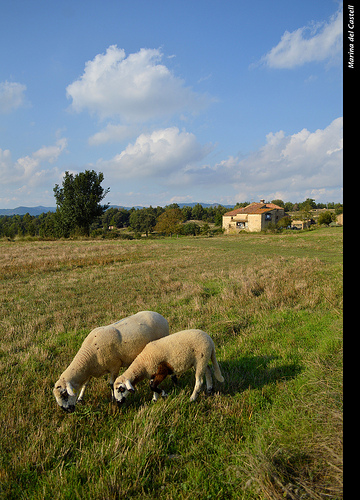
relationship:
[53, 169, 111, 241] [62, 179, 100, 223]
tree has leaves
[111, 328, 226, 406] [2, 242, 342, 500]
sheep grazing in field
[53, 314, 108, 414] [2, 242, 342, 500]
sheep grazing in a field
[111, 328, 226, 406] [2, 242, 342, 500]
sheep grazing in a field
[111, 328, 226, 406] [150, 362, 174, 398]
sheep with leg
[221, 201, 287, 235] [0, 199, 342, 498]
house in a field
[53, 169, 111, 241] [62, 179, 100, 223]
tree with leaves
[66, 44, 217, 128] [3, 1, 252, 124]
cloud in blue sky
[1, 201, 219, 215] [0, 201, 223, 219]
mountains in distance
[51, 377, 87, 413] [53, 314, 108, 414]
head of sheep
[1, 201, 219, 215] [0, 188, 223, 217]
mountain on horizon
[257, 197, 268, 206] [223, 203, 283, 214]
chimney on a roof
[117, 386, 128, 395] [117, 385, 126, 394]
markings with black markings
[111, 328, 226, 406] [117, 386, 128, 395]
sheep has an markings